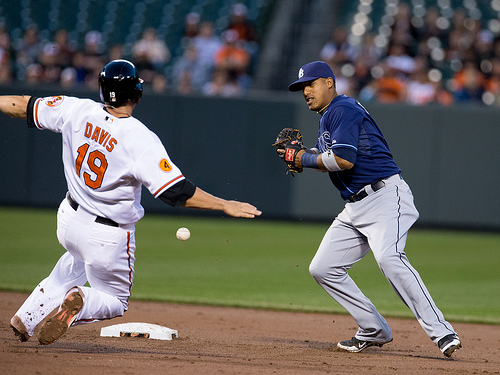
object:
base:
[97, 320, 178, 342]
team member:
[74, 143, 101, 180]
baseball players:
[0, 58, 265, 345]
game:
[2, 57, 500, 375]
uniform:
[308, 92, 464, 362]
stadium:
[0, 0, 499, 375]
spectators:
[129, 24, 173, 67]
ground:
[2, 211, 499, 375]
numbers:
[82, 149, 109, 191]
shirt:
[316, 94, 404, 199]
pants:
[306, 172, 459, 343]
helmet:
[96, 59, 144, 109]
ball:
[173, 224, 191, 242]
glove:
[273, 136, 307, 178]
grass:
[0, 209, 499, 327]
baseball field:
[0, 208, 499, 374]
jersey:
[23, 94, 198, 226]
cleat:
[458, 344, 465, 347]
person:
[274, 59, 467, 357]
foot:
[335, 333, 394, 353]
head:
[297, 60, 337, 114]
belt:
[345, 172, 404, 206]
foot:
[437, 333, 465, 358]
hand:
[226, 199, 263, 220]